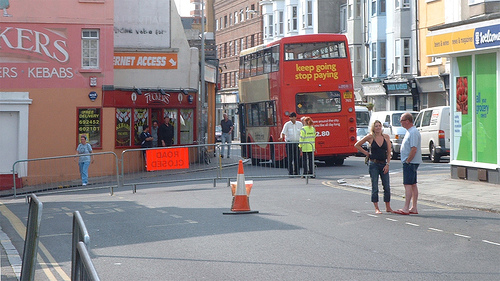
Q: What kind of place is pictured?
A: It is a road.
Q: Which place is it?
A: It is a road.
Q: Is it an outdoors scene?
A: Yes, it is outdoors.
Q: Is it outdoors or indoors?
A: It is outdoors.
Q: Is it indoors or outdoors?
A: It is outdoors.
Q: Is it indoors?
A: No, it is outdoors.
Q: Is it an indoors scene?
A: No, it is outdoors.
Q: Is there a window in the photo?
A: Yes, there is a window.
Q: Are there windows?
A: Yes, there is a window.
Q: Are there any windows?
A: Yes, there is a window.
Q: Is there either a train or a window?
A: Yes, there is a window.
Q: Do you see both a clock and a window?
A: No, there is a window but no clocks.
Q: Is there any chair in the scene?
A: No, there are no chairs.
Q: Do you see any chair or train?
A: No, there are no chairs or trains.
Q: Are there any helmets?
A: No, there are no helmets.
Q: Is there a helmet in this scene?
A: No, there are no helmets.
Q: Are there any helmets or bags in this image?
A: No, there are no helmets or bags.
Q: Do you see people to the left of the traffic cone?
A: Yes, there is a person to the left of the traffic cone.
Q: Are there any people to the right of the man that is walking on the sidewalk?
A: No, the person is to the left of the man.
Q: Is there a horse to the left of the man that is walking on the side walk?
A: No, there is a person to the left of the man.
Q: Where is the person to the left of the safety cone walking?
A: The person is walking on the sidewalk.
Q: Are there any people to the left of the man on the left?
A: Yes, there is a person to the left of the man.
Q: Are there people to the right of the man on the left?
A: No, the person is to the left of the man.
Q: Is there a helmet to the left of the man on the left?
A: No, there is a person to the left of the man.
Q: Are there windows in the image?
A: Yes, there is a window.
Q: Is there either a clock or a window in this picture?
A: Yes, there is a window.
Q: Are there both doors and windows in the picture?
A: Yes, there are both a window and a door.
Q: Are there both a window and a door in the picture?
A: Yes, there are both a window and a door.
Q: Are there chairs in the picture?
A: No, there are no chairs.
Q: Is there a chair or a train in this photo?
A: No, there are no chairs or trains.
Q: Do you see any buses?
A: Yes, there is a bus.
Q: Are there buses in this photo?
A: Yes, there is a bus.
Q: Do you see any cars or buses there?
A: Yes, there is a bus.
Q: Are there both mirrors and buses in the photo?
A: No, there is a bus but no mirrors.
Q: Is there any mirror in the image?
A: No, there are no mirrors.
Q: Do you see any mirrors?
A: No, there are no mirrors.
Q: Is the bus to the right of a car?
A: No, the bus is to the left of a car.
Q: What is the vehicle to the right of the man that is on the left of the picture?
A: The vehicle is a bus.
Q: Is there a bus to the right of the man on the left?
A: Yes, there is a bus to the right of the man.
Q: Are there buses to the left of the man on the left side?
A: No, the bus is to the right of the man.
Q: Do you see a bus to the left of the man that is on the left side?
A: No, the bus is to the right of the man.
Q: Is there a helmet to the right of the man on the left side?
A: No, there is a bus to the right of the man.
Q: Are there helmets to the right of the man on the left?
A: No, there is a bus to the right of the man.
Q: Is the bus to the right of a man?
A: Yes, the bus is to the right of a man.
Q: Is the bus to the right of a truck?
A: No, the bus is to the right of a man.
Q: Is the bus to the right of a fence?
A: No, the bus is to the right of a man.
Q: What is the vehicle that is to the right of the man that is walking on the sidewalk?
A: The vehicle is a bus.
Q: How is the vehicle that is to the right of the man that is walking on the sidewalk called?
A: The vehicle is a bus.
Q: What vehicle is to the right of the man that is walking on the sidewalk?
A: The vehicle is a bus.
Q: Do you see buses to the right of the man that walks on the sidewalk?
A: Yes, there is a bus to the right of the man.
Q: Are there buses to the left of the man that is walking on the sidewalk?
A: No, the bus is to the right of the man.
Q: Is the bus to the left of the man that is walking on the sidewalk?
A: No, the bus is to the right of the man.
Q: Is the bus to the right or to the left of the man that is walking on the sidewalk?
A: The bus is to the right of the man.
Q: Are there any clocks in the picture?
A: No, there are no clocks.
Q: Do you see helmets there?
A: No, there are no helmets.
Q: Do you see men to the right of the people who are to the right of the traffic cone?
A: Yes, there is a man to the right of the people.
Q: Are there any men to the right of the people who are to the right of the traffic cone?
A: Yes, there is a man to the right of the people.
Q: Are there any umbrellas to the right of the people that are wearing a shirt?
A: No, there is a man to the right of the people.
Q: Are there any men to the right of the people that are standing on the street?
A: Yes, there is a man to the right of the people.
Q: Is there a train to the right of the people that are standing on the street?
A: No, there is a man to the right of the people.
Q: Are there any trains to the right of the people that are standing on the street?
A: No, there is a man to the right of the people.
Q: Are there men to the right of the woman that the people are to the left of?
A: Yes, there is a man to the right of the woman.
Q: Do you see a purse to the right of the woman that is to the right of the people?
A: No, there is a man to the right of the woman.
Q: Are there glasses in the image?
A: No, there are no glasses.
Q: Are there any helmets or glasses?
A: No, there are no glasses or helmets.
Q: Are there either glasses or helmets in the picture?
A: No, there are no glasses or helmets.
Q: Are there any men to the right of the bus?
A: No, the man is to the left of the bus.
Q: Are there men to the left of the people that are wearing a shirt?
A: Yes, there is a man to the left of the people.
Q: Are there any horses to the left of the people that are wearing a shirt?
A: No, there is a man to the left of the people.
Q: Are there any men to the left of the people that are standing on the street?
A: Yes, there is a man to the left of the people.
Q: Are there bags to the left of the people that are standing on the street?
A: No, there is a man to the left of the people.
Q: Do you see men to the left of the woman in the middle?
A: Yes, there is a man to the left of the woman.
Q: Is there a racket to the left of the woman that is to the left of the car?
A: No, there is a man to the left of the woman.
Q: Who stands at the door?
A: The man stands at the door.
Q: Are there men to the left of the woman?
A: Yes, there is a man to the left of the woman.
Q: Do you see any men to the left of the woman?
A: Yes, there is a man to the left of the woman.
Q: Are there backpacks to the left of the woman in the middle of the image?
A: No, there is a man to the left of the woman.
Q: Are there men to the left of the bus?
A: Yes, there is a man to the left of the bus.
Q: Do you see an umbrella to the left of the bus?
A: No, there is a man to the left of the bus.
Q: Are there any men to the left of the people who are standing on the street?
A: Yes, there is a man to the left of the people.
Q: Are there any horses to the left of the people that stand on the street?
A: No, there is a man to the left of the people.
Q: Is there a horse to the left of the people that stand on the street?
A: No, there is a man to the left of the people.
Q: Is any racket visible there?
A: No, there are no rackets.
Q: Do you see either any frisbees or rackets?
A: No, there are no rackets or frisbees.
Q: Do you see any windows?
A: Yes, there is a window.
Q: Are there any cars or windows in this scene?
A: Yes, there is a window.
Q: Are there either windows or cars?
A: Yes, there is a window.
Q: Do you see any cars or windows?
A: Yes, there is a window.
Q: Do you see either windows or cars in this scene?
A: Yes, there is a window.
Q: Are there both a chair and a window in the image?
A: No, there is a window but no chairs.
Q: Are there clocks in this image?
A: No, there are no clocks.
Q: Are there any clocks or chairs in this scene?
A: No, there are no clocks or chairs.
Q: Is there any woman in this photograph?
A: Yes, there is a woman.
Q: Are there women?
A: Yes, there is a woman.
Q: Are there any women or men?
A: Yes, there is a woman.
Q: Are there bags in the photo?
A: No, there are no bags.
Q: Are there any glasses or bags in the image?
A: No, there are no bags or glasses.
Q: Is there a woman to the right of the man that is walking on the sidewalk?
A: Yes, there is a woman to the right of the man.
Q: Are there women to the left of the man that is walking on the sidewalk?
A: No, the woman is to the right of the man.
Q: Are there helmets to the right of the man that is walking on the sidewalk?
A: No, there is a woman to the right of the man.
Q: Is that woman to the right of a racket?
A: No, the woman is to the right of a man.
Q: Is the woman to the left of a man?
A: No, the woman is to the right of a man.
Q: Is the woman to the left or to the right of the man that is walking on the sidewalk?
A: The woman is to the right of the man.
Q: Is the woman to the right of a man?
A: Yes, the woman is to the right of a man.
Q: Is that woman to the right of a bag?
A: No, the woman is to the right of a man.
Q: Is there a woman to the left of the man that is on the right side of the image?
A: Yes, there is a woman to the left of the man.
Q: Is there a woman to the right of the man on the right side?
A: No, the woman is to the left of the man.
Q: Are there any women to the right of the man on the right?
A: No, the woman is to the left of the man.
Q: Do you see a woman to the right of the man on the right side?
A: No, the woman is to the left of the man.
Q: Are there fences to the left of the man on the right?
A: No, there is a woman to the left of the man.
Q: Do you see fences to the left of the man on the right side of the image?
A: No, there is a woman to the left of the man.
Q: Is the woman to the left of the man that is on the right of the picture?
A: Yes, the woman is to the left of the man.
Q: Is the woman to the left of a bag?
A: No, the woman is to the left of the man.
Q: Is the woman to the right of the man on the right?
A: No, the woman is to the left of the man.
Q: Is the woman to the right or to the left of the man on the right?
A: The woman is to the left of the man.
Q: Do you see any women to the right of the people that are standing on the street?
A: Yes, there is a woman to the right of the people.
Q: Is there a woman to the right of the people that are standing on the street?
A: Yes, there is a woman to the right of the people.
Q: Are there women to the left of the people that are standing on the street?
A: No, the woman is to the right of the people.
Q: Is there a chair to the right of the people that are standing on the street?
A: No, there is a woman to the right of the people.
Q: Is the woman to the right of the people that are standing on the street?
A: Yes, the woman is to the right of the people.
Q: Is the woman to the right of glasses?
A: No, the woman is to the right of the people.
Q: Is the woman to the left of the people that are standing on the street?
A: No, the woman is to the right of the people.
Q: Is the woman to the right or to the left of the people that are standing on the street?
A: The woman is to the right of the people.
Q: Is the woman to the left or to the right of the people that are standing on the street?
A: The woman is to the right of the people.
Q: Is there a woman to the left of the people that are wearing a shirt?
A: Yes, there is a woman to the left of the people.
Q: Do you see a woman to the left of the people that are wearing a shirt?
A: Yes, there is a woman to the left of the people.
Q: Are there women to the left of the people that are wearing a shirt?
A: Yes, there is a woman to the left of the people.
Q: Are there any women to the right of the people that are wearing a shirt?
A: No, the woman is to the left of the people.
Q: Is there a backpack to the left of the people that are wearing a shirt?
A: No, there is a woman to the left of the people.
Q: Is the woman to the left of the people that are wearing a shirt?
A: Yes, the woman is to the left of the people.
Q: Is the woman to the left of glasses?
A: No, the woman is to the left of the people.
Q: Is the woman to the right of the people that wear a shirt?
A: No, the woman is to the left of the people.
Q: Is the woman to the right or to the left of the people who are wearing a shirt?
A: The woman is to the left of the people.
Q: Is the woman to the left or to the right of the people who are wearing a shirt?
A: The woman is to the left of the people.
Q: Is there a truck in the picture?
A: No, there are no trucks.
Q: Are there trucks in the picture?
A: No, there are no trucks.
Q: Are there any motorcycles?
A: No, there are no motorcycles.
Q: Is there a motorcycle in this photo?
A: No, there are no motorcycles.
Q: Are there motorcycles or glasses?
A: No, there are no motorcycles or glasses.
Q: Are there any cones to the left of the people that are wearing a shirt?
A: Yes, there is a cone to the left of the people.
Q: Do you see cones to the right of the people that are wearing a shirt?
A: No, the cone is to the left of the people.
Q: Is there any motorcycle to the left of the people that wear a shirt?
A: No, there is a cone to the left of the people.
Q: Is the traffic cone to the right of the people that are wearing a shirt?
A: No, the traffic cone is to the left of the people.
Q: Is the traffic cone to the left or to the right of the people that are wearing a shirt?
A: The traffic cone is to the left of the people.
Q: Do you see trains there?
A: No, there are no trains.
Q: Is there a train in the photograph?
A: No, there are no trains.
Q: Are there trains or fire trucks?
A: No, there are no trains or fire trucks.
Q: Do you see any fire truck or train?
A: No, there are no trains or fire trucks.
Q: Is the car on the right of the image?
A: Yes, the car is on the right of the image.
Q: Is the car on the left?
A: No, the car is on the right of the image.